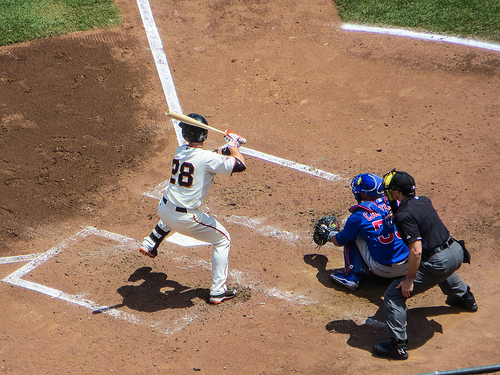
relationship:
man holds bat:
[139, 111, 246, 322] [159, 108, 246, 145]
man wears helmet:
[139, 111, 246, 322] [178, 114, 206, 139]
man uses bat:
[139, 111, 246, 322] [159, 108, 246, 145]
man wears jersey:
[139, 111, 246, 322] [162, 146, 236, 198]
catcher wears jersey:
[319, 177, 416, 290] [356, 197, 408, 267]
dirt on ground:
[1, 32, 140, 244] [6, 18, 495, 369]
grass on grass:
[5, 1, 123, 46] [0, 0, 124, 46]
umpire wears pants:
[371, 168, 478, 359] [382, 238, 471, 354]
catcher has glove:
[319, 177, 416, 290] [317, 214, 338, 243]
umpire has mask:
[371, 168, 478, 359] [382, 172, 395, 214]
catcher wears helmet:
[319, 177, 416, 290] [354, 176, 387, 192]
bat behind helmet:
[159, 108, 246, 145] [178, 114, 206, 139]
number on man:
[167, 158, 194, 181] [139, 111, 246, 322]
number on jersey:
[167, 158, 194, 181] [162, 146, 236, 198]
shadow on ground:
[88, 266, 215, 323] [6, 18, 495, 369]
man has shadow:
[139, 111, 246, 322] [88, 266, 215, 323]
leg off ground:
[138, 217, 168, 262] [6, 18, 495, 369]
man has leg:
[139, 111, 246, 322] [138, 217, 168, 262]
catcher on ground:
[319, 177, 416, 290] [6, 18, 495, 369]